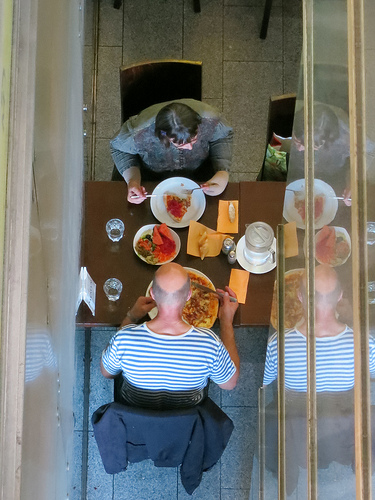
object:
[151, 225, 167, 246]
food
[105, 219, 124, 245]
glass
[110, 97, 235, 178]
shirt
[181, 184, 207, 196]
fork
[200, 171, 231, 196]
hand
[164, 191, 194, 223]
food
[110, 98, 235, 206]
woman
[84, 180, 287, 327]
table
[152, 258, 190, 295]
bald head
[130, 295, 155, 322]
hand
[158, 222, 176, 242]
food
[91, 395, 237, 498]
jacket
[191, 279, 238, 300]
knife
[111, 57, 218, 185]
chair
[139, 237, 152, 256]
food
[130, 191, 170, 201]
utensil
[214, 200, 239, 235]
napkins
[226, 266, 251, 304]
napkin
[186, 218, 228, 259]
orange napkin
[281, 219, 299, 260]
orange napkin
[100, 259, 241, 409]
man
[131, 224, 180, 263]
white plate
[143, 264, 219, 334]
white plate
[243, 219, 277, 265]
pitcher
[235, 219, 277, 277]
plate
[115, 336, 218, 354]
striped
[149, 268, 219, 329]
food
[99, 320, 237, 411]
shirt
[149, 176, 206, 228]
plate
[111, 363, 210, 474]
chair